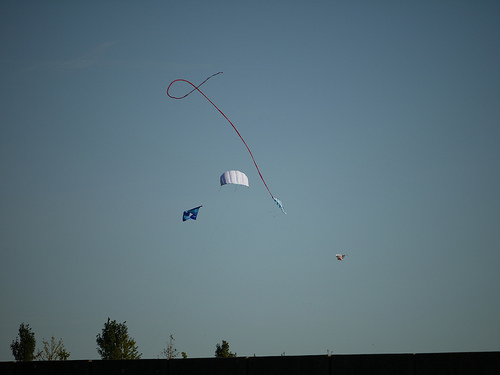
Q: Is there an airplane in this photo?
A: No, there are no airplanes.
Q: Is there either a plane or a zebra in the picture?
A: No, there are no airplanes or zebras.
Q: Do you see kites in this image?
A: Yes, there is a kite.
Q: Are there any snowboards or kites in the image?
A: Yes, there is a kite.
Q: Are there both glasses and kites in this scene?
A: No, there is a kite but no glasses.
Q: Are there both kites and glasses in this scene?
A: No, there is a kite but no glasses.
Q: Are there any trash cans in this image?
A: No, there are no trash cans.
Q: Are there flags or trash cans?
A: No, there are no trash cans or flags.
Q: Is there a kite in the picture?
A: Yes, there is a kite.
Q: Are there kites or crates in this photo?
A: Yes, there is a kite.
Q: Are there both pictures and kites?
A: No, there is a kite but no pictures.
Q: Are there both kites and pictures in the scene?
A: No, there is a kite but no pictures.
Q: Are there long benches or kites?
A: Yes, there is a long kite.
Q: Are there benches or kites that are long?
A: Yes, the kite is long.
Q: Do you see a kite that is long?
A: Yes, there is a long kite.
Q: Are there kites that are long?
A: Yes, there is a kite that is long.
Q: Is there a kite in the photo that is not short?
A: Yes, there is a long kite.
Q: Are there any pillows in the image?
A: No, there are no pillows.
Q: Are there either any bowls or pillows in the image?
A: No, there are no pillows or bowls.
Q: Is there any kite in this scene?
A: Yes, there is a kite.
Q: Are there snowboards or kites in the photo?
A: Yes, there is a kite.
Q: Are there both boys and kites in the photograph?
A: No, there is a kite but no boys.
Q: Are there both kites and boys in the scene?
A: No, there is a kite but no boys.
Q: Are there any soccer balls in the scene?
A: No, there are no soccer balls.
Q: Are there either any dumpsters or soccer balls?
A: No, there are no soccer balls or dumpsters.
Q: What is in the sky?
A: The kite is in the sky.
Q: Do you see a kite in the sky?
A: Yes, there is a kite in the sky.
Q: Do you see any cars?
A: No, there are no cars.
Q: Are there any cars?
A: No, there are no cars.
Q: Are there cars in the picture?
A: No, there are no cars.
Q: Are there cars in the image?
A: No, there are no cars.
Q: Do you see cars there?
A: No, there are no cars.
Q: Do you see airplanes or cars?
A: No, there are no cars or airplanes.